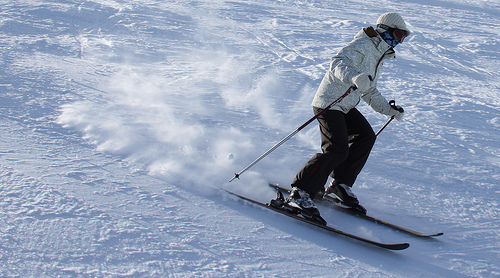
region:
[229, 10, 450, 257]
Man is skiing on hill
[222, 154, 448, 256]
man wearing a pair of skis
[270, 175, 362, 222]
man wearing a pair of skiboots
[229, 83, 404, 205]
man carrying two ski poles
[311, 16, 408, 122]
man wearing white jacket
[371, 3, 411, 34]
man wearing a white hat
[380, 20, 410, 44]
man wearing ski goggles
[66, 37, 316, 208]
snow dust flying behind skier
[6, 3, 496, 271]
snow is bright and white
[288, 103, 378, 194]
man wearing black ski pants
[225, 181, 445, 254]
a set of black skis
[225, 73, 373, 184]
black ski poles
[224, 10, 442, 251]
a person standing on skis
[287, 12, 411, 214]
a person wearing a white coat and black pants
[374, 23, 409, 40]
a pair of goggles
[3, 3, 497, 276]
snow covered ground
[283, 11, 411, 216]
a person wearing a white hat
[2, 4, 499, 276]
tracks in the snow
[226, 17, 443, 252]
the person is skiing downhill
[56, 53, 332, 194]
snow flying up into the air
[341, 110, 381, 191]
the leg on a skier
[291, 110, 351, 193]
the leg on a skier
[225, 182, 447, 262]
a pair of black snow skies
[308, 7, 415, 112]
a skier wearing a white jacket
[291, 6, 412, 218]
a skier wearing black ski pants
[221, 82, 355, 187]
a silver and black ski pole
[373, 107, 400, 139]
a black ski pole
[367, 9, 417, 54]
a skier wearing a white cap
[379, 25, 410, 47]
a skier wearing goggles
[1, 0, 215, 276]
thick white snow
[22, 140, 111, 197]
fresh snow on the ground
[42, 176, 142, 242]
marks in the white snow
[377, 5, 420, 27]
white cap on person's head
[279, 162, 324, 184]
wrinkles in black pants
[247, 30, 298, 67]
long tracks in the snow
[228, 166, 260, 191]
end of the ski pole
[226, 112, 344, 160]
long black ski pole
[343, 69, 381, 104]
white glove on man's hand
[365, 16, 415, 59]
scarf around man's face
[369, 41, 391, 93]
long black zipper in front of white jacket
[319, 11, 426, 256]
person skiing down mountain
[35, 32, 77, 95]
white snow on hill side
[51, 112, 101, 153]
white snow on hill side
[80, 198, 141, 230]
white snow on hill side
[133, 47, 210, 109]
white snow on hill side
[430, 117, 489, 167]
white snow on hill side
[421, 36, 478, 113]
white snow on hill side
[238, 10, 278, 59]
white snow on hill side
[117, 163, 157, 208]
white snow on hill side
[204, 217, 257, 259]
white snow on hill side